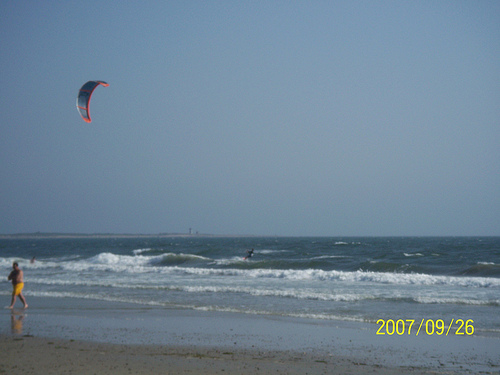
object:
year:
[374, 315, 416, 341]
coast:
[1, 229, 227, 238]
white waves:
[42, 257, 81, 272]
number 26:
[454, 317, 474, 337]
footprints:
[141, 336, 318, 373]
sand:
[47, 282, 492, 371]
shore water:
[0, 276, 499, 347]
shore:
[38, 298, 378, 365]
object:
[73, 74, 103, 122]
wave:
[330, 237, 371, 247]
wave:
[92, 248, 213, 265]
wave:
[250, 247, 295, 253]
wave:
[8, 266, 497, 290]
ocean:
[2, 236, 498, 305]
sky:
[0, 0, 499, 234]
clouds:
[178, 71, 479, 219]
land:
[0, 225, 277, 240]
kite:
[74, 77, 109, 123]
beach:
[3, 251, 498, 372]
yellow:
[11, 281, 25, 293]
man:
[8, 259, 28, 311]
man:
[244, 248, 254, 261]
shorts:
[10, 281, 25, 296]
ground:
[4, 265, 459, 369]